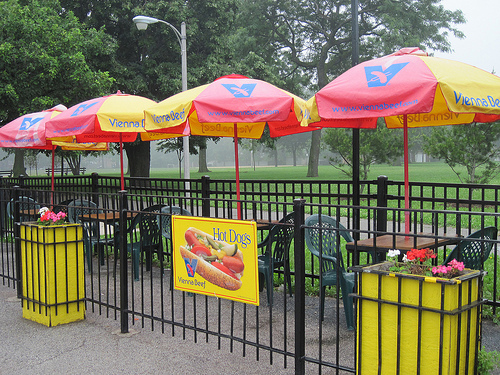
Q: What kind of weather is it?
A: Raining.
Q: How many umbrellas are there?
A: Four.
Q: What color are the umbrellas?
A: Red and yellow.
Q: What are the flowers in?
A: Flower bed.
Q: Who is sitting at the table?
A: No one.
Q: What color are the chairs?
A: Green.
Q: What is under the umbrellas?
A: Tables.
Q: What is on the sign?
A: Hot Dogs.